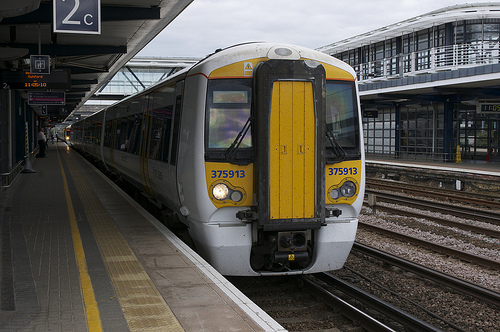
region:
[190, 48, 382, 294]
The train is yellow and white.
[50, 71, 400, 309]
The train is at a train station.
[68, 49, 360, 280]
The train is long.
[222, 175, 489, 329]
The track is brown.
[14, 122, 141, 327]
One man is waiting for the train.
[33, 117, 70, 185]
He is standing.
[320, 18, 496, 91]
Many windows are on the building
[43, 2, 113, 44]
The sign is white and black.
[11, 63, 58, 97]
The sign is lit.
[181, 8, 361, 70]
The sky is overcast.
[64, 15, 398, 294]
grey and yellow train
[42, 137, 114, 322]
long yellow line on cement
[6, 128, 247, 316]
waiting area for passengers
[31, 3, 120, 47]
grey sign for passengers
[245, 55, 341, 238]
tall yellow door on train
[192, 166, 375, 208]
small headlights on train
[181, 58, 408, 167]
big windshields with wipers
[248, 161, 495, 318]
steel train tracks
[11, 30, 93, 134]
signs with lettering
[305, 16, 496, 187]
large building next to track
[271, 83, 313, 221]
yellow wooden slats on the front of a train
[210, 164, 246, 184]
the number 375913 on the front of a train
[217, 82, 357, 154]
the front two windows of a train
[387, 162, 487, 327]
railroad tracks beside a train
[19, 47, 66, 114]
signs along the outside of a train depot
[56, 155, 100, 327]
a yellow caution line outside a train depot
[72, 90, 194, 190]
a long line of train cars on a commuter train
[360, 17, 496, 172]
a two story train depot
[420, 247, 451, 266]
gravel between railroad tracks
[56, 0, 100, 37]
a sign that says 2c on it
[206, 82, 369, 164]
black windows on front of train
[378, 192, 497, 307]
gravel between train tracks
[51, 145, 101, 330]
yellow stripe on platform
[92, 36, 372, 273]
yellow white and black train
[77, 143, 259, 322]
white stripe on train platform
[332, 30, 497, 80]
balcony on building in background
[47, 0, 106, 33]
platform 2c sign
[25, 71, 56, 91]
orange digital numbers on sign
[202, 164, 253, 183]
train car number 375913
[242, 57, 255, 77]
yellow hazardous sign on front of train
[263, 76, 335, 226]
Yellow door on bus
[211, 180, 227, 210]
One headlight is on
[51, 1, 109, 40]
Sign says 2 c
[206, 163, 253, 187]
Blue numbers on train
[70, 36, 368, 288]
Large yellow, black and white train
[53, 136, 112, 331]
Yellow stripe on walkway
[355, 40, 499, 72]
White railing on building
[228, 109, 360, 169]
Two black wiper blades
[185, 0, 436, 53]
White clouds in the sky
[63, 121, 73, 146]
Train behind closer train